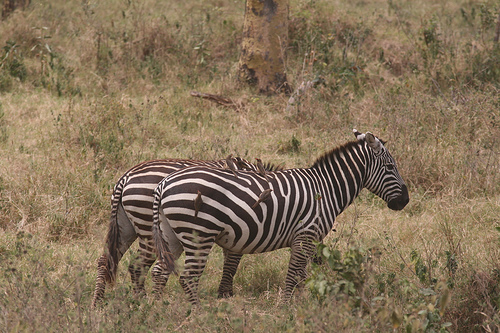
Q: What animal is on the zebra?
A: Birds.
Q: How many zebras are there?
A: Two.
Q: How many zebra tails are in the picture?
A: Two.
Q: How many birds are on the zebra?
A: Four.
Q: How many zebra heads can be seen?
A: One.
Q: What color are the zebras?
A: Black and White.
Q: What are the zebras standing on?
A: Grass.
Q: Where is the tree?
A: Beside the zebras.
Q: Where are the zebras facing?
A: Right.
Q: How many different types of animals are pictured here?
A: Two.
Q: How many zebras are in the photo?
A: Two.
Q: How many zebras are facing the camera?
A: Zero.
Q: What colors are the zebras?
A: Black and white.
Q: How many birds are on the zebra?
A: Four.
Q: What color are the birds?
A: Black.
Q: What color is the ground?
A: Tan.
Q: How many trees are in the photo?
A: One.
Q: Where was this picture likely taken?
A: Africa.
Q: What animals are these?
A: Zebras.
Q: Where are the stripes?
A: On the zebras.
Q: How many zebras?
A: Two.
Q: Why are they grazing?
A: Hunger.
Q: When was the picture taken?
A: Daytime.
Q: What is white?
A: Stripes.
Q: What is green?
A: Grass.